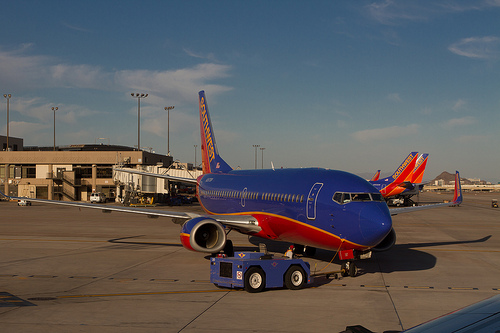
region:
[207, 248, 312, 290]
A cart bring driven to guide the airplane.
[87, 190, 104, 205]
The rear of a white van.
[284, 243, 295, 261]
A man driving a cart, towing an airplane.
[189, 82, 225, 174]
The tail wing of the aircraft being pulled.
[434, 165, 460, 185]
A brown mountain in the background.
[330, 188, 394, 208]
The windshield area of the plane being towed.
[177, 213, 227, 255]
The right engine of the aircraft being towed.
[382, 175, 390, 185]
An American flag on he tail of a plane not being towed.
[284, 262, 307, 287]
The front tire of the vehicle towing a plane.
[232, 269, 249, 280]
A no smoking sign.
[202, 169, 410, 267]
the plane is blue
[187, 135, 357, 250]
the plane is blue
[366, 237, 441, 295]
shadow on the ground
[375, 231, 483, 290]
shadow on the ground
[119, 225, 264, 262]
shadow on the ground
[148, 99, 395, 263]
blue red and orange airplane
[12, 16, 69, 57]
white clouds in blue sky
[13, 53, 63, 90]
white clouds in blue sky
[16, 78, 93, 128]
white clouds in blue sky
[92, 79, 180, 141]
white clouds in blue sky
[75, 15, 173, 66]
white clouds in blue sky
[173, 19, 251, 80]
white clouds in blue sky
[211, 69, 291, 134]
white clouds in blue sky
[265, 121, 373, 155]
white clouds in blue sky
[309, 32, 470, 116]
white clouds in blue sky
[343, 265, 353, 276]
wheels on the plane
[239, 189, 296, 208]
windows on the plane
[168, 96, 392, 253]
the plane is blue and red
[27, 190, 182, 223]
the wing of the plane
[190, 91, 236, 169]
the tail of the plane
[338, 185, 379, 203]
windshield of the plane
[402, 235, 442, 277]
a shadow on the ground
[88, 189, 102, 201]
a white van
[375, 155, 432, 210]
two airplanes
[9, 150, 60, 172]
a building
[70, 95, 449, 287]
the plane is mostly blue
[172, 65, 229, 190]
the tail is red and blue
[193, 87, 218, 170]
the letters are orange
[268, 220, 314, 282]
man driving a vehicle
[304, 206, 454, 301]
shadow of the plane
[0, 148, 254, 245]
the wings are silver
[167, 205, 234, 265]
the engine is red, orange and blue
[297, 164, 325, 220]
the door is blue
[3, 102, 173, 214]
the building is beige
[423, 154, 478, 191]
a mountain in the distance